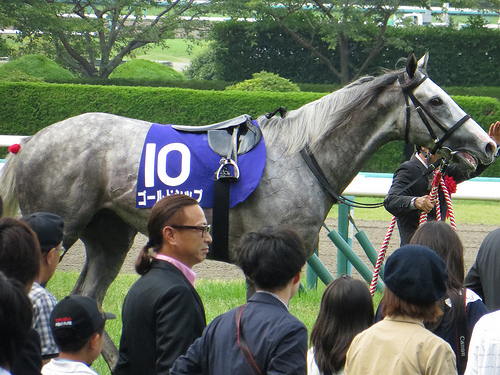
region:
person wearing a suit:
[122, 179, 219, 373]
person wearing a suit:
[170, 222, 325, 372]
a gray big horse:
[2, 48, 484, 329]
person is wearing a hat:
[15, 212, 82, 372]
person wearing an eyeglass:
[104, 185, 233, 373]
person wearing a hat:
[341, 236, 473, 373]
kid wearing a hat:
[34, 287, 121, 373]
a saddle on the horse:
[129, 94, 280, 209]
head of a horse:
[395, 44, 497, 184]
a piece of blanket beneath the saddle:
[132, 106, 273, 216]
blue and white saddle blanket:
[127, 113, 269, 215]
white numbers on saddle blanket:
[134, 136, 197, 191]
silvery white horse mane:
[257, 73, 387, 156]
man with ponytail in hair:
[111, 192, 227, 374]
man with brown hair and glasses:
[107, 192, 219, 374]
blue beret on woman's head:
[380, 242, 450, 312]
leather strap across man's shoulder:
[224, 299, 274, 374]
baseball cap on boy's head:
[42, 290, 117, 342]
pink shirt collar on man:
[154, 250, 200, 285]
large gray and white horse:
[6, 50, 498, 372]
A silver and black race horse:
[0, 51, 496, 371]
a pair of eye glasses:
[168, 223, 213, 237]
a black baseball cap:
[50, 293, 115, 322]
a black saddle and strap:
[170, 111, 260, 261]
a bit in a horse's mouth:
[439, 142, 461, 157]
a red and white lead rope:
[366, 160, 454, 295]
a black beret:
[380, 245, 445, 303]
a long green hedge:
[0, 80, 499, 175]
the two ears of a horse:
[405, 49, 429, 79]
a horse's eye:
[426, 94, 444, 106]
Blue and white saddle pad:
[132, 108, 274, 229]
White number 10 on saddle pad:
[135, 137, 208, 197]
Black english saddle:
[162, 103, 269, 188]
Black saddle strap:
[198, 171, 250, 266]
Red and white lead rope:
[358, 147, 463, 314]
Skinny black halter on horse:
[391, 62, 481, 172]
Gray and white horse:
[0, 38, 497, 358]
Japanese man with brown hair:
[114, 197, 232, 374]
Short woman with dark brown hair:
[297, 257, 366, 372]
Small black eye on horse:
[427, 91, 443, 113]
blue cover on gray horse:
[127, 115, 277, 220]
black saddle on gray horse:
[181, 94, 280, 171]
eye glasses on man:
[157, 220, 228, 240]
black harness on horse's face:
[383, 94, 498, 169]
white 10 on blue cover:
[144, 124, 196, 193]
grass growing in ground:
[190, 292, 260, 339]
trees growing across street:
[62, 20, 227, 112]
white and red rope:
[359, 190, 411, 312]